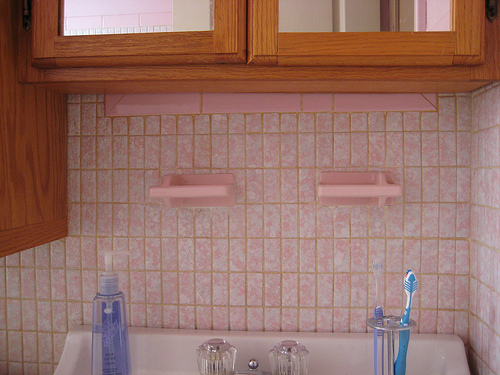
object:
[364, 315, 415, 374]
holder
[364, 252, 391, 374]
toothbrush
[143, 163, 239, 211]
soap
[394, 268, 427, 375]
toothbrush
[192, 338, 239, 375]
knob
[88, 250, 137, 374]
soap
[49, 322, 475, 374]
sink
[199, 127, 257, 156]
tile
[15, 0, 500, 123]
cabinet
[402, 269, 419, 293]
head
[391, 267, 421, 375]
brush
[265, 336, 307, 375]
handle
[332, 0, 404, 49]
door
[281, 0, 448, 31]
mirror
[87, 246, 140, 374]
bottle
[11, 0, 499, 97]
cupboard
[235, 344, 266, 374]
tap